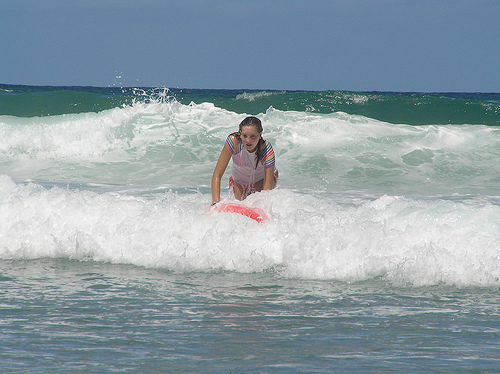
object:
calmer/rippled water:
[35, 273, 233, 371]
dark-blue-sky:
[42, 12, 232, 58]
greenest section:
[11, 87, 95, 112]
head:
[235, 114, 265, 149]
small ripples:
[225, 302, 398, 372]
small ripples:
[32, 329, 140, 371]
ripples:
[178, 283, 203, 308]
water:
[376, 95, 490, 138]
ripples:
[69, 217, 189, 343]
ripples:
[165, 267, 201, 286]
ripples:
[113, 242, 226, 335]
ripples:
[86, 240, 130, 263]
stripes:
[263, 149, 271, 161]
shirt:
[227, 131, 275, 183]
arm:
[210, 133, 233, 204]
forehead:
[240, 123, 257, 135]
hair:
[243, 118, 263, 128]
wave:
[0, 86, 484, 294]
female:
[211, 115, 281, 208]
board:
[207, 196, 267, 224]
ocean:
[17, 58, 481, 359]